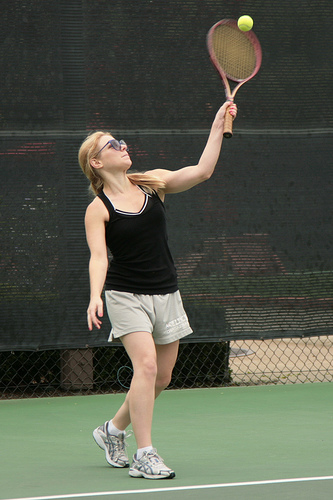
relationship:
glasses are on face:
[106, 139, 126, 149] [94, 129, 134, 173]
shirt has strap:
[103, 195, 172, 295] [98, 194, 112, 208]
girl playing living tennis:
[78, 98, 240, 479] [137, 13, 279, 204]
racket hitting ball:
[205, 13, 268, 134] [233, 12, 257, 31]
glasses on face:
[106, 139, 126, 149] [92, 127, 135, 175]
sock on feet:
[136, 450, 153, 458] [87, 416, 180, 498]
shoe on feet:
[129, 449, 174, 481] [87, 416, 180, 498]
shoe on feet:
[94, 420, 129, 471] [87, 416, 180, 498]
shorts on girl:
[106, 292, 186, 340] [78, 98, 240, 479]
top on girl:
[97, 182, 180, 294] [78, 98, 240, 479]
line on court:
[2, 475, 331, 499] [1, 383, 328, 497]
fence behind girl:
[2, 0, 332, 402] [78, 98, 240, 479]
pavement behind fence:
[228, 336, 327, 388] [13, 93, 329, 414]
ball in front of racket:
[237, 10, 254, 34] [207, 16, 262, 140]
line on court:
[176, 469, 329, 495] [151, 410, 328, 495]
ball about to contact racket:
[230, 5, 252, 40] [192, 6, 277, 150]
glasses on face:
[106, 139, 126, 149] [90, 132, 131, 168]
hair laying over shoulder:
[125, 172, 165, 194] [126, 167, 165, 205]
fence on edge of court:
[2, 0, 332, 402] [12, 15, 329, 313]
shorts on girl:
[104, 289, 192, 350] [78, 98, 240, 479]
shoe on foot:
[120, 447, 175, 481] [117, 331, 188, 484]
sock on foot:
[107, 419, 121, 437] [90, 419, 130, 471]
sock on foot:
[136, 449, 150, 454] [133, 445, 170, 480]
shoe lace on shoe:
[143, 446, 164, 462] [129, 449, 174, 481]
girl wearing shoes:
[78, 98, 240, 479] [89, 417, 179, 483]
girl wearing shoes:
[78, 98, 240, 479] [82, 416, 180, 490]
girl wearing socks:
[78, 98, 240, 479] [86, 408, 172, 458]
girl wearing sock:
[78, 98, 240, 479] [106, 417, 124, 436]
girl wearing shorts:
[78, 98, 240, 479] [104, 289, 192, 350]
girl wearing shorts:
[78, 98, 240, 479] [101, 284, 198, 345]